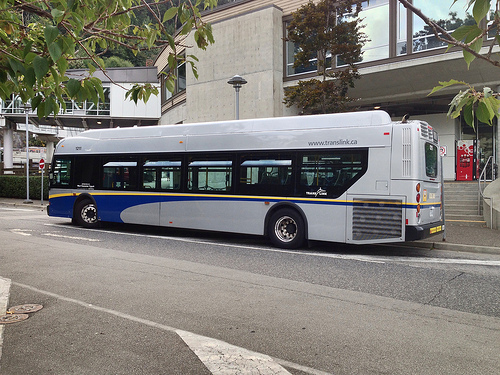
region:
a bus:
[41, 109, 471, 256]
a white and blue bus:
[36, 100, 496, 294]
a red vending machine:
[440, 122, 491, 193]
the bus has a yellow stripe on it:
[28, 80, 495, 284]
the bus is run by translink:
[39, 120, 440, 246]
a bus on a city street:
[11, 85, 483, 373]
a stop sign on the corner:
[28, 160, 49, 215]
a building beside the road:
[152, 12, 499, 214]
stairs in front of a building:
[436, 172, 498, 257]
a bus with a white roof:
[37, 96, 447, 255]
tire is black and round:
[244, 190, 314, 257]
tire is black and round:
[264, 196, 301, 246]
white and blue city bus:
[33, 121, 488, 269]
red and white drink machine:
[450, 128, 482, 186]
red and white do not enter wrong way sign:
[31, 147, 52, 214]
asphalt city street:
[9, 213, 498, 341]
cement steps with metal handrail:
[446, 172, 497, 256]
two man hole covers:
[1, 293, 55, 330]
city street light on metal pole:
[217, 67, 265, 135]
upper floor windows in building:
[284, 9, 496, 81]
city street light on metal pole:
[18, 98, 40, 213]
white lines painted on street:
[3, 206, 494, 300]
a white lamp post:
[220, 68, 252, 118]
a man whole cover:
[0, 284, 49, 338]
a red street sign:
[27, 151, 54, 176]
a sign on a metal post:
[29, 144, 49, 210]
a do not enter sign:
[30, 150, 52, 178]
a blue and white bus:
[31, 104, 483, 267]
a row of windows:
[89, 151, 371, 206]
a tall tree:
[275, 5, 395, 127]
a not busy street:
[13, 88, 485, 372]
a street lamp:
[222, 62, 253, 122]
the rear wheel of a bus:
[265, 204, 308, 251]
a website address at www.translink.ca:
[300, 137, 363, 153]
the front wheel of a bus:
[67, 197, 108, 225]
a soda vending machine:
[448, 137, 483, 181]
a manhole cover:
[7, 300, 44, 315]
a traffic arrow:
[8, 214, 96, 249]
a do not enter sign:
[34, 150, 49, 203]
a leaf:
[160, 76, 178, 96]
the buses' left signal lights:
[415, 180, 426, 224]